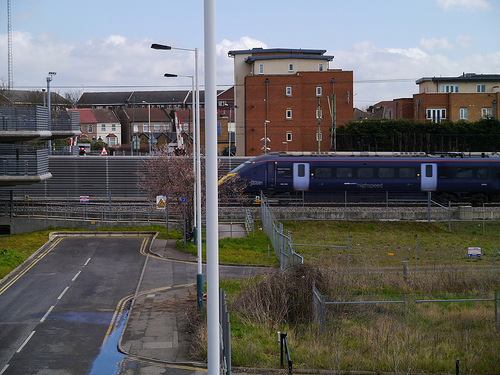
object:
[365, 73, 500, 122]
buildings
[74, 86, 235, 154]
buildings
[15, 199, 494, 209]
tracks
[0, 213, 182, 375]
road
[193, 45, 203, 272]
white pole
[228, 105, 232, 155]
white pole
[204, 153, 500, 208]
train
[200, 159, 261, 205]
nose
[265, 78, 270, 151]
pole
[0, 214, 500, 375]
ground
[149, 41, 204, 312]
street light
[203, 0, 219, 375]
pole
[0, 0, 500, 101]
blue sky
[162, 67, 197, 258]
street light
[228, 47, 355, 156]
building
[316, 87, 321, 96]
window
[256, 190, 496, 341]
fence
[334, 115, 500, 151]
trees row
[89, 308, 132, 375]
puddle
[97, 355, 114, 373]
water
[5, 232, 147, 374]
pavement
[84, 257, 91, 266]
stripes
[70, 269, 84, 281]
stripes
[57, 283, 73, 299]
stripes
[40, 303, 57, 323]
stripes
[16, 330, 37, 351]
stripes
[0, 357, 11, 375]
stripes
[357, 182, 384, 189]
writing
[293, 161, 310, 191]
door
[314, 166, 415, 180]
windows